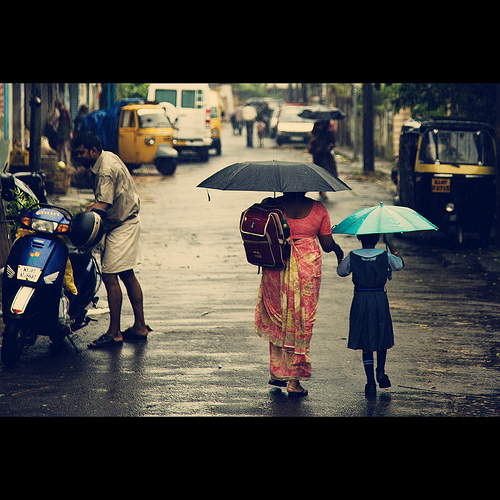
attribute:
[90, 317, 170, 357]
black sandals —  black 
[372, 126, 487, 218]
vehicle — yellow, black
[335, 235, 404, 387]
girl — uniform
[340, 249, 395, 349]
dress — blue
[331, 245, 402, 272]
shirt — light blue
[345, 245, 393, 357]
dress —  dark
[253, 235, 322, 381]
skirt — yellow  , pink green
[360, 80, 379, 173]
pole — long 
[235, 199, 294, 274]
backpack — maroon, brown 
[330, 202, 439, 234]
umbrella —  green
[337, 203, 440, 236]
umbrella — small, green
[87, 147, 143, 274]
outfit — khaki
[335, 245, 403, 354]
uniform —  blue,  for school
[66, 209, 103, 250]
helmet —  motorcycle's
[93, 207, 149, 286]
shorts — men's white 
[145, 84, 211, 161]
van — white, cargo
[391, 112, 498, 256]
taxi — tuk tuk three wheel 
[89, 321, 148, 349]
sandals — black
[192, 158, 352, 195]
black canopy — black 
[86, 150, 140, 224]
shirt — grey, short-sleeve